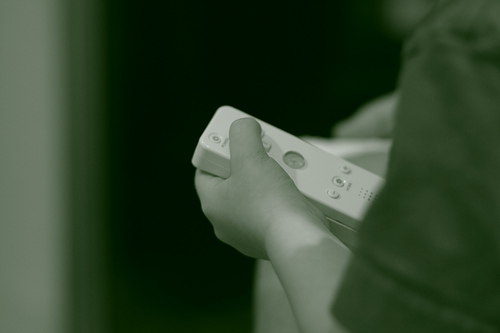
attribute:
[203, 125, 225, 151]
button — power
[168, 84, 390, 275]
hand — small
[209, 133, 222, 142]
button — circular, small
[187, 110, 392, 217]
controller — white, Wii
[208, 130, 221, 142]
button — power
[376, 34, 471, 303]
shirt — dark, colored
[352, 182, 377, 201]
holes — small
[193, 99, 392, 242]
game controller — white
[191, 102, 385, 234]
wii — white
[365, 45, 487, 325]
shirt — black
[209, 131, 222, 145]
button — round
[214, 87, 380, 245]
controller — small, white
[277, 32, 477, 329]
person — small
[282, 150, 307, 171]
button — circle, clear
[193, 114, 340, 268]
hand — small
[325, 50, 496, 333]
shirt — short sleeved